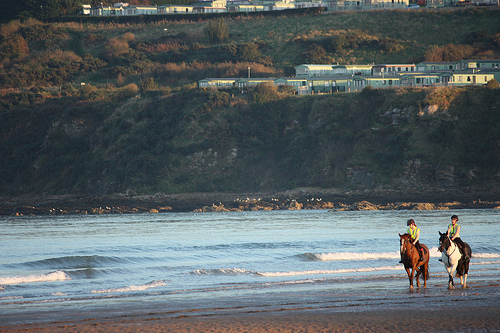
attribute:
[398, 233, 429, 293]
horse — brown, tan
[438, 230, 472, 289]
pony — black, white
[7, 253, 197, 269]
wave — white, blue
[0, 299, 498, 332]
beach — wet, sand, sandy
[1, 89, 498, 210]
hill — grassy, brown, bushy, grass, rocky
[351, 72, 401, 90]
building — mulitcolored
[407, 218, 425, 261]
woman — riding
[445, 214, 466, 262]
lady — light, little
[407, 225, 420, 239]
shirt — green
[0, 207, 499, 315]
ocean — big, blue, wavy